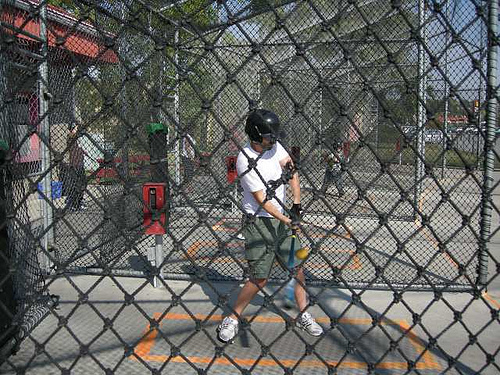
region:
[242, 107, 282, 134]
A black helmet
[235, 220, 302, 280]
Gray shorts in the photo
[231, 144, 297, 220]
White t-shirt in the photo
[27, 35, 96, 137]
A building in the background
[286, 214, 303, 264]
A baseball bat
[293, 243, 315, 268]
A baseball in the air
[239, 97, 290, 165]
man is wearing black helmet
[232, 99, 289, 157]
man is wearing black helmet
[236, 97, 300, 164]
man is wearing black helmet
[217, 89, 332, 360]
man trying to hit the ball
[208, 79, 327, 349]
man trying to hit the ball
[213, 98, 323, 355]
man trying to hit the ball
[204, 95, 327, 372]
man trying to hit the ball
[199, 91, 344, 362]
man trying to hit the ball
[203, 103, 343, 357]
man in batting cage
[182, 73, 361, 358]
man holding a baseball bat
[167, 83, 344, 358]
man hitting a ball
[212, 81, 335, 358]
man wearing a white t-shirt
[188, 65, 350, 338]
man wearing olive green shorts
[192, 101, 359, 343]
man wearing black gloves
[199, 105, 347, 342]
man wearing black helmet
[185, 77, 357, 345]
man wearing white sneakers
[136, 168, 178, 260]
red box in batting cage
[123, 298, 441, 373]
yellow lines on concrete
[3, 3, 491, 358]
a bunch of baseball batting cages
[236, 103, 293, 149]
a black batting helmet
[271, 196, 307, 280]
a swinging baseball bat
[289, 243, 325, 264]
a baseball in flight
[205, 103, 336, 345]
a boy practices batting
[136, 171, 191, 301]
pay meter for the batting cage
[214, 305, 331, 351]
a pair of white sneakers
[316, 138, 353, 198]
a small boy learning to bat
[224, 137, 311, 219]
a white t-shirt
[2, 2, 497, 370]
black string of net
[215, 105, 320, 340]
boy swinging bat at ball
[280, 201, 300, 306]
two hands on baseball bat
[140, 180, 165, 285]
red box on metal pole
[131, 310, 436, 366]
orange paint designating batter's box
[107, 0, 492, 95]
blue of daytime sky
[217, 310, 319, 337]
white sneakers on feet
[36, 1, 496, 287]
poles for suspended net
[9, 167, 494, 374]
concrete surface of batting cages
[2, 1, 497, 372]
black net over batting cage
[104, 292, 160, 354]
knots in black net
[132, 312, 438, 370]
orange painted box on cement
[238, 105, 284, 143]
A black batting helmet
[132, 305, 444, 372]
An orange box on the ground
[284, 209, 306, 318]
A blue baseball bat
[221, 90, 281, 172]
a man wearing a helmet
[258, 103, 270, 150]
a black helmet on the head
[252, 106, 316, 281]
a person holding a baseball bat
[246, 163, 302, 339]
a person holding a bat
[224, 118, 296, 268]
a person swinging a bat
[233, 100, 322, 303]
a person swinging a baseball bat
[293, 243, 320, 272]
a baseball hitting a back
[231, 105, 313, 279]
a boy wearing shorts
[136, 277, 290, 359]
yellow lines on the ground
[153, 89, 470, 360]
a black chain fence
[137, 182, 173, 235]
red box behind fence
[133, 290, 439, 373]
yellow box on ground